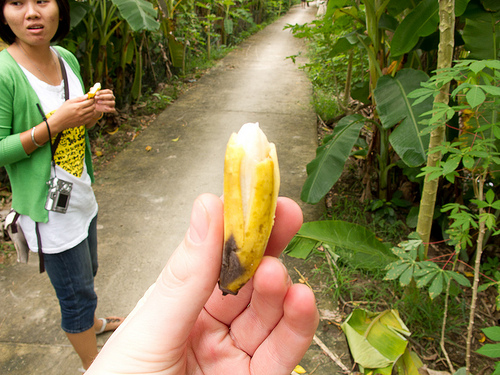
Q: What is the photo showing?
A: It is showing a path.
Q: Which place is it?
A: It is a path.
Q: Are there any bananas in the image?
A: Yes, there is a banana.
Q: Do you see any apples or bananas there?
A: Yes, there is a banana.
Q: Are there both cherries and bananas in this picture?
A: No, there is a banana but no cherries.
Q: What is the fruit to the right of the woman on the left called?
A: The fruit is a banana.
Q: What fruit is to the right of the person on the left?
A: The fruit is a banana.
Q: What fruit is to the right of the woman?
A: The fruit is a banana.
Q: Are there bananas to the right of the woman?
A: Yes, there is a banana to the right of the woman.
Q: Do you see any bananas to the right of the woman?
A: Yes, there is a banana to the right of the woman.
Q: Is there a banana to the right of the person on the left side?
A: Yes, there is a banana to the right of the woman.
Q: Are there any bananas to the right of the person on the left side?
A: Yes, there is a banana to the right of the woman.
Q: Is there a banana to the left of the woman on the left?
A: No, the banana is to the right of the woman.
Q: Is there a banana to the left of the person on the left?
A: No, the banana is to the right of the woman.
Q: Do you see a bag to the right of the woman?
A: No, there is a banana to the right of the woman.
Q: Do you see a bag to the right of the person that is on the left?
A: No, there is a banana to the right of the woman.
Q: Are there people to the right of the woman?
A: Yes, there is a person to the right of the woman.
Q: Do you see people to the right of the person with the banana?
A: Yes, there is a person to the right of the woman.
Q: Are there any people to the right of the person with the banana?
A: Yes, there is a person to the right of the woman.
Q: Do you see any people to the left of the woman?
A: No, the person is to the right of the woman.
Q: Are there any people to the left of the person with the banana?
A: No, the person is to the right of the woman.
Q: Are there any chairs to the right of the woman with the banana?
A: No, there is a person to the right of the woman.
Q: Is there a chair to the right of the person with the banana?
A: No, there is a person to the right of the woman.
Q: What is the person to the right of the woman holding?
A: The person is holding the banana.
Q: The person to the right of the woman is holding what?
A: The person is holding the banana.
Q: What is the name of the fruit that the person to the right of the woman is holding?
A: The fruit is a banana.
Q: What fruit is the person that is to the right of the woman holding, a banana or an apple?
A: The person is holding a banana.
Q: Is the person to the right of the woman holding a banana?
A: Yes, the person is holding a banana.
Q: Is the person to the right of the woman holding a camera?
A: No, the person is holding a banana.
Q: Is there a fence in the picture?
A: No, there are no fences.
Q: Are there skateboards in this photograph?
A: No, there are no skateboards.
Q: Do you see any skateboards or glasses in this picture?
A: No, there are no skateboards or glasses.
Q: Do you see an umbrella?
A: No, there are no umbrellas.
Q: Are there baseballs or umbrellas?
A: No, there are no umbrellas or baseballs.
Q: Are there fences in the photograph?
A: No, there are no fences.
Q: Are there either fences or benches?
A: No, there are no fences or benches.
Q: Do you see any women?
A: Yes, there is a woman.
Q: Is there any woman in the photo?
A: Yes, there is a woman.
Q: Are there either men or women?
A: Yes, there is a woman.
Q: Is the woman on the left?
A: Yes, the woman is on the left of the image.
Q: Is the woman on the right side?
A: No, the woman is on the left of the image.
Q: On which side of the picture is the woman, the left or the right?
A: The woman is on the left of the image.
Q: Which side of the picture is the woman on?
A: The woman is on the left of the image.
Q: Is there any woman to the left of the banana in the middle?
A: Yes, there is a woman to the left of the banana.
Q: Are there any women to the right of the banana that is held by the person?
A: No, the woman is to the left of the banana.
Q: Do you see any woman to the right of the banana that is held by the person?
A: No, the woman is to the left of the banana.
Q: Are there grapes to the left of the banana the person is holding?
A: No, there is a woman to the left of the banana.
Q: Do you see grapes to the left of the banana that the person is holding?
A: No, there is a woman to the left of the banana.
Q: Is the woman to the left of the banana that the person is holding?
A: Yes, the woman is to the left of the banana.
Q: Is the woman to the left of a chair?
A: No, the woman is to the left of the banana.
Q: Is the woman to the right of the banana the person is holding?
A: No, the woman is to the left of the banana.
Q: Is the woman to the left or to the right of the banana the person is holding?
A: The woman is to the left of the banana.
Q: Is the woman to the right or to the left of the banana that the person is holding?
A: The woman is to the left of the banana.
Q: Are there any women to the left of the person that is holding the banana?
A: Yes, there is a woman to the left of the person.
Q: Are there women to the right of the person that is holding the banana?
A: No, the woman is to the left of the person.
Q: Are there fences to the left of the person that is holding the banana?
A: No, there is a woman to the left of the person.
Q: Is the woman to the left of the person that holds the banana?
A: Yes, the woman is to the left of the person.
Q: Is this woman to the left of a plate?
A: No, the woman is to the left of the person.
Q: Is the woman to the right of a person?
A: No, the woman is to the left of a person.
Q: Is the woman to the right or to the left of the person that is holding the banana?
A: The woman is to the left of the person.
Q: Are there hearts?
A: Yes, there is a heart.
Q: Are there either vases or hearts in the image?
A: Yes, there is a heart.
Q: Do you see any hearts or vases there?
A: Yes, there is a heart.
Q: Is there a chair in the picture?
A: No, there are no chairs.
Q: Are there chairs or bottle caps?
A: No, there are no chairs or bottle caps.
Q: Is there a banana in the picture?
A: Yes, there is a banana.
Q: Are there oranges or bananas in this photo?
A: Yes, there is a banana.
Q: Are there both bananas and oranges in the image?
A: No, there is a banana but no oranges.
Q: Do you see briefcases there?
A: No, there are no briefcases.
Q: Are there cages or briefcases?
A: No, there are no briefcases or cages.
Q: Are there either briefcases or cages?
A: No, there are no briefcases or cages.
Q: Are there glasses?
A: No, there are no glasses.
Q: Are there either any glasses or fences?
A: No, there are no glasses or fences.